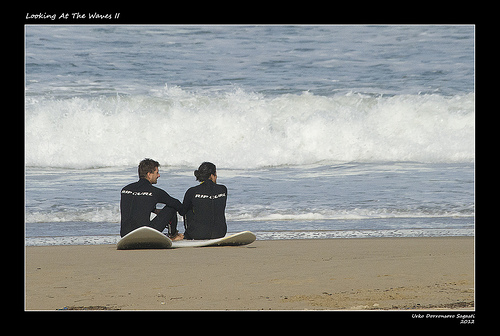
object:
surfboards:
[174, 230, 259, 253]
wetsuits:
[177, 180, 228, 240]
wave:
[25, 90, 472, 170]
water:
[23, 24, 474, 246]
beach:
[22, 236, 474, 310]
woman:
[183, 159, 228, 240]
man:
[115, 157, 181, 241]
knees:
[156, 200, 175, 213]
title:
[22, 12, 120, 20]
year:
[457, 318, 475, 326]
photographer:
[407, 312, 473, 325]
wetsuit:
[118, 181, 182, 237]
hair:
[135, 159, 156, 183]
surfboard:
[117, 219, 174, 256]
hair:
[194, 160, 216, 181]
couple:
[117, 160, 229, 240]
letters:
[192, 193, 201, 198]